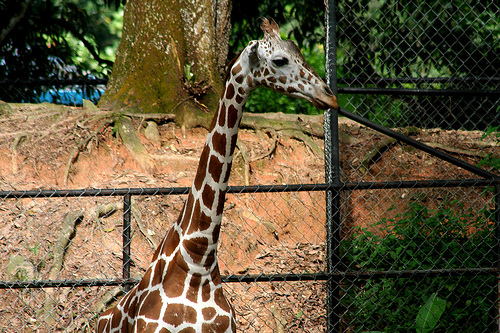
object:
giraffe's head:
[233, 16, 340, 113]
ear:
[247, 38, 260, 66]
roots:
[247, 112, 327, 190]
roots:
[0, 96, 155, 183]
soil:
[0, 102, 499, 242]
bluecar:
[0, 45, 105, 107]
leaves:
[0, 0, 126, 102]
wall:
[335, 0, 500, 332]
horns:
[260, 15, 282, 41]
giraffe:
[84, 16, 338, 332]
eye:
[271, 55, 290, 67]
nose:
[314, 81, 338, 109]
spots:
[157, 277, 231, 330]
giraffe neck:
[153, 72, 266, 263]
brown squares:
[213, 62, 255, 128]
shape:
[226, 83, 235, 99]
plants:
[327, 194, 499, 332]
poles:
[2, 178, 496, 333]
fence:
[0, 0, 499, 333]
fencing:
[1, 0, 500, 333]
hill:
[0, 100, 497, 332]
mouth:
[314, 97, 338, 110]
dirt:
[0, 140, 208, 188]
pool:
[0, 45, 106, 108]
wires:
[1, 0, 500, 333]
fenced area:
[0, 0, 499, 333]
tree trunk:
[98, 0, 231, 110]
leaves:
[344, 0, 500, 136]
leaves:
[346, 194, 499, 332]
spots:
[129, 13, 177, 53]